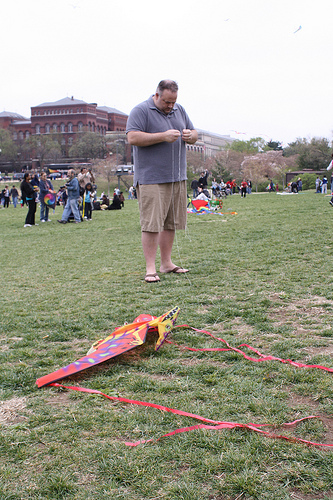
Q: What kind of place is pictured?
A: It is a park.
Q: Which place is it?
A: It is a park.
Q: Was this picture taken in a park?
A: Yes, it was taken in a park.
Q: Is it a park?
A: Yes, it is a park.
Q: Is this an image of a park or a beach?
A: It is showing a park.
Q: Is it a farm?
A: No, it is a park.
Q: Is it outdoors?
A: Yes, it is outdoors.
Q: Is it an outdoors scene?
A: Yes, it is outdoors.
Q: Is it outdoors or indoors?
A: It is outdoors.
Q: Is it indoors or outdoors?
A: It is outdoors.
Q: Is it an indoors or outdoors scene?
A: It is outdoors.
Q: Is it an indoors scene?
A: No, it is outdoors.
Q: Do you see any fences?
A: No, there are no fences.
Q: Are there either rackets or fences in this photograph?
A: No, there are no fences or rackets.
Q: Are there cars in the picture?
A: No, there are no cars.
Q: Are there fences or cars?
A: No, there are no cars or fences.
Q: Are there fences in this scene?
A: No, there are no fences.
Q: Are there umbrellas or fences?
A: No, there are no fences or umbrellas.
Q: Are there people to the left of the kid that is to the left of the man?
A: Yes, there are people to the left of the kid.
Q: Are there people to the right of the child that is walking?
A: No, the people are to the left of the kid.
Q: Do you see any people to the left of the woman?
A: Yes, there are people to the left of the woman.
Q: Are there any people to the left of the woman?
A: Yes, there are people to the left of the woman.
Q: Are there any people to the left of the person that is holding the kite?
A: Yes, there are people to the left of the woman.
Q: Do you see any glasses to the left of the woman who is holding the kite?
A: No, there are people to the left of the woman.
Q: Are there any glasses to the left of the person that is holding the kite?
A: No, there are people to the left of the woman.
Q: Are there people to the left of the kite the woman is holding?
A: Yes, there are people to the left of the kite.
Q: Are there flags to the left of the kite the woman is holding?
A: No, there are people to the left of the kite.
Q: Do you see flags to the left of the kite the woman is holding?
A: No, there are people to the left of the kite.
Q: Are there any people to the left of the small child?
A: Yes, there are people to the left of the kid.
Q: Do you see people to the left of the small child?
A: Yes, there are people to the left of the kid.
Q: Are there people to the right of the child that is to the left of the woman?
A: No, the people are to the left of the child.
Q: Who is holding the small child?
A: The people are holding the kid.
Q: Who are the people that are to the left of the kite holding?
A: The people are holding the kid.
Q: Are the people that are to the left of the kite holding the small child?
A: Yes, the people are holding the kid.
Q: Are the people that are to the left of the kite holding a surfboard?
A: No, the people are holding the kid.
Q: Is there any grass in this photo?
A: Yes, there is grass.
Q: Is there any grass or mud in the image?
A: Yes, there is grass.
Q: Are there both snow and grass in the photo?
A: No, there is grass but no snow.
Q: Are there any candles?
A: No, there are no candles.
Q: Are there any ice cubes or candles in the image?
A: No, there are no candles or ice cubes.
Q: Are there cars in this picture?
A: No, there are no cars.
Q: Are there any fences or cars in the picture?
A: No, there are no cars or fences.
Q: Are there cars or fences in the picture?
A: No, there are no cars or fences.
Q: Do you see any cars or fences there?
A: No, there are no cars or fences.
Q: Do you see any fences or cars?
A: No, there are no fences or cars.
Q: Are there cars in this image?
A: No, there are no cars.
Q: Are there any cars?
A: No, there are no cars.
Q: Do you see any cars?
A: No, there are no cars.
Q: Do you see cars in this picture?
A: No, there are no cars.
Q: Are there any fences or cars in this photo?
A: No, there are no cars or fences.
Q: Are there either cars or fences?
A: No, there are no cars or fences.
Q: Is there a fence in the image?
A: No, there are no fences.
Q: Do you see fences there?
A: No, there are no fences.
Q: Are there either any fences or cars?
A: No, there are no fences or cars.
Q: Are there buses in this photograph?
A: No, there are no buses.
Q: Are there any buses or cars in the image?
A: No, there are no buses or cars.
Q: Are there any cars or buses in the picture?
A: No, there are no buses or cars.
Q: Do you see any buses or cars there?
A: No, there are no buses or cars.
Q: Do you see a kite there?
A: Yes, there is a kite.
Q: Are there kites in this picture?
A: Yes, there is a kite.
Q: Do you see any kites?
A: Yes, there is a kite.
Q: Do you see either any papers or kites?
A: Yes, there is a kite.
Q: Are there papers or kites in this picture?
A: Yes, there is a kite.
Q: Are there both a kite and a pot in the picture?
A: No, there is a kite but no pots.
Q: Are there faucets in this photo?
A: No, there are no faucets.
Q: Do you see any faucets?
A: No, there are no faucets.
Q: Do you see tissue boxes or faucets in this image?
A: No, there are no faucets or tissue boxes.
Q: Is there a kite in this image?
A: Yes, there is a kite.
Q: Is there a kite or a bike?
A: Yes, there is a kite.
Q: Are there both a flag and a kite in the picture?
A: No, there is a kite but no flags.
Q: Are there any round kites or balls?
A: Yes, there is a round kite.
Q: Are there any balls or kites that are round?
A: Yes, the kite is round.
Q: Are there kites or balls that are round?
A: Yes, the kite is round.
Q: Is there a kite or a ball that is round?
A: Yes, the kite is round.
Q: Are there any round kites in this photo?
A: Yes, there is a round kite.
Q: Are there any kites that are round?
A: Yes, there is a kite that is round.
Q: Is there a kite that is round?
A: Yes, there is a kite that is round.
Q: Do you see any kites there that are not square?
A: Yes, there is a round kite.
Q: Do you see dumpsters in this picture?
A: No, there are no dumpsters.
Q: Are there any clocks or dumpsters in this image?
A: No, there are no dumpsters or clocks.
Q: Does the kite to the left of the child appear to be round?
A: Yes, the kite is round.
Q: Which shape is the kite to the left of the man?
A: The kite is round.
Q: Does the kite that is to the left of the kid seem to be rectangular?
A: No, the kite is round.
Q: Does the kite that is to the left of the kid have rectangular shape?
A: No, the kite is round.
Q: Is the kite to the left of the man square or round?
A: The kite is round.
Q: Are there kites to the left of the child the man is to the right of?
A: Yes, there is a kite to the left of the child.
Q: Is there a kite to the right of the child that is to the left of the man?
A: No, the kite is to the left of the child.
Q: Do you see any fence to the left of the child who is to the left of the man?
A: No, there is a kite to the left of the child.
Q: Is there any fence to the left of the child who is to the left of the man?
A: No, there is a kite to the left of the child.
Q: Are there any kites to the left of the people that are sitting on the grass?
A: Yes, there is a kite to the left of the people.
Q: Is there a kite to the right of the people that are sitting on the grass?
A: No, the kite is to the left of the people.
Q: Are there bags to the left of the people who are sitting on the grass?
A: No, there is a kite to the left of the people.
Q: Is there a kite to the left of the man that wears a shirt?
A: Yes, there is a kite to the left of the man.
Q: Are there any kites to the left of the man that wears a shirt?
A: Yes, there is a kite to the left of the man.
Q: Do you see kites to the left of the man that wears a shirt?
A: Yes, there is a kite to the left of the man.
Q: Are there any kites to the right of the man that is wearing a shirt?
A: No, the kite is to the left of the man.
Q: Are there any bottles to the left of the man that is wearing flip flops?
A: No, there is a kite to the left of the man.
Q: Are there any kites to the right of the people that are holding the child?
A: Yes, there is a kite to the right of the people.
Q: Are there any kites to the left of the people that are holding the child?
A: No, the kite is to the right of the people.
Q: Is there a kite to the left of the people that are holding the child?
A: No, the kite is to the right of the people.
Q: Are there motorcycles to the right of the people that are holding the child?
A: No, there is a kite to the right of the people.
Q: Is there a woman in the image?
A: Yes, there is a woman.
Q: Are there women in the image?
A: Yes, there is a woman.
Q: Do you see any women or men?
A: Yes, there is a woman.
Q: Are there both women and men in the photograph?
A: Yes, there are both a woman and a man.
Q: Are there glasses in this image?
A: No, there are no glasses.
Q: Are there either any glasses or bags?
A: No, there are no glasses or bags.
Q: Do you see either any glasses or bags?
A: No, there are no glasses or bags.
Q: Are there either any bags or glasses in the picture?
A: No, there are no glasses or bags.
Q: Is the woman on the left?
A: Yes, the woman is on the left of the image.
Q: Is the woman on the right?
A: No, the woman is on the left of the image.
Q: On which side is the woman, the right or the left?
A: The woman is on the left of the image.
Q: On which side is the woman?
A: The woman is on the left of the image.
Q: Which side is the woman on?
A: The woman is on the left of the image.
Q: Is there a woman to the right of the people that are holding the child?
A: Yes, there is a woman to the right of the people.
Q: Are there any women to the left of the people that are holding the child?
A: No, the woman is to the right of the people.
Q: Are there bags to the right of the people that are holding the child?
A: No, there is a woman to the right of the people.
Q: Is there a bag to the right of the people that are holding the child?
A: No, there is a woman to the right of the people.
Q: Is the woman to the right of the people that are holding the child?
A: Yes, the woman is to the right of the people.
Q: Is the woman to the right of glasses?
A: No, the woman is to the right of the people.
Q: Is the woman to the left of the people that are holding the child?
A: No, the woman is to the right of the people.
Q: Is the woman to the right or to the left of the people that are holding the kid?
A: The woman is to the right of the people.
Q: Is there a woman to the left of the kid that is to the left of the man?
A: Yes, there is a woman to the left of the kid.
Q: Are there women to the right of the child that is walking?
A: No, the woman is to the left of the kid.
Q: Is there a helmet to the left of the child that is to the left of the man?
A: No, there is a woman to the left of the child.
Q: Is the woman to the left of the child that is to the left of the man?
A: Yes, the woman is to the left of the kid.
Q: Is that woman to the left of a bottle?
A: No, the woman is to the left of the kid.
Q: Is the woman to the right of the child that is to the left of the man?
A: No, the woman is to the left of the kid.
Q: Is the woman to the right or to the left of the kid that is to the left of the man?
A: The woman is to the left of the child.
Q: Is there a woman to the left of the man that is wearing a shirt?
A: Yes, there is a woman to the left of the man.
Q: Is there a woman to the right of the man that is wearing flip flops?
A: No, the woman is to the left of the man.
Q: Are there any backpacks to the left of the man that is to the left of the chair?
A: No, there is a woman to the left of the man.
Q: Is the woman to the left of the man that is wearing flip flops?
A: Yes, the woman is to the left of the man.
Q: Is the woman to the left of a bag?
A: No, the woman is to the left of the man.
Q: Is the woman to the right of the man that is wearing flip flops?
A: No, the woman is to the left of the man.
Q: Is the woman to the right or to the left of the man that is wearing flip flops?
A: The woman is to the left of the man.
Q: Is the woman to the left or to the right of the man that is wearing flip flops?
A: The woman is to the left of the man.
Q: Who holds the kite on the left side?
A: The woman holds the kite.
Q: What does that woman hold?
A: The woman holds the kite.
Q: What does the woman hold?
A: The woman holds the kite.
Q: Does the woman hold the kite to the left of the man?
A: Yes, the woman holds the kite.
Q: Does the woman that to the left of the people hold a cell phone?
A: No, the woman holds the kite.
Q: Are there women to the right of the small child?
A: Yes, there is a woman to the right of the kid.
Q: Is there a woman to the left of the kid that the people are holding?
A: No, the woman is to the right of the kid.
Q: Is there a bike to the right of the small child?
A: No, there is a woman to the right of the child.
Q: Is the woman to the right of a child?
A: Yes, the woman is to the right of a child.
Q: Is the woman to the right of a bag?
A: No, the woman is to the right of a child.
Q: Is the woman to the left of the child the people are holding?
A: No, the woman is to the right of the child.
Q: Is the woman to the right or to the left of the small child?
A: The woman is to the right of the kid.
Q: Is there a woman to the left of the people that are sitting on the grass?
A: Yes, there is a woman to the left of the people.